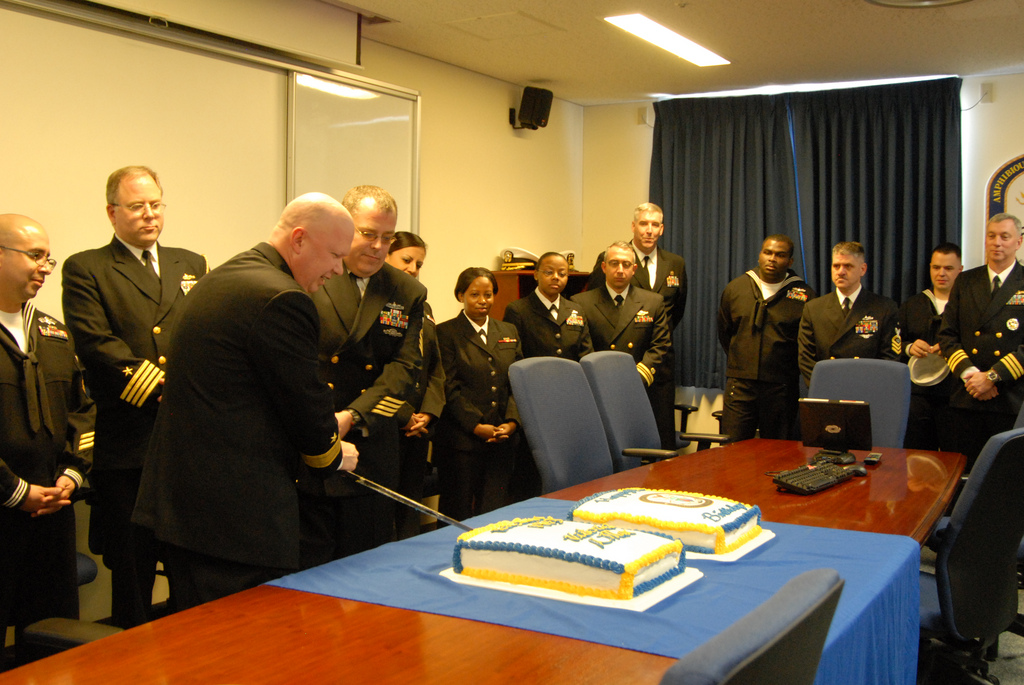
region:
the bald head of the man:
[275, 184, 362, 290]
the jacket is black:
[142, 258, 339, 538]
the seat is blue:
[502, 356, 623, 509]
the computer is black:
[790, 389, 888, 466]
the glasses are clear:
[24, 249, 60, 268]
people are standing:
[717, 209, 1022, 416]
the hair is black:
[446, 262, 495, 294]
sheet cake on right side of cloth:
[440, 508, 713, 617]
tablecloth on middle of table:
[265, 472, 934, 684]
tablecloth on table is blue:
[257, 472, 937, 684]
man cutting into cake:
[120, 186, 475, 611]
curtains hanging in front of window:
[635, 74, 980, 416]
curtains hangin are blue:
[635, 71, 980, 398]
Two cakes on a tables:
[582, 504, 691, 574]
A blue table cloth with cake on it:
[705, 576, 798, 624]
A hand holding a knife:
[339, 449, 358, 472]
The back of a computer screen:
[807, 401, 863, 443]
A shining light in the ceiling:
[637, 20, 660, 37]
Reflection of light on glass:
[302, 79, 329, 88]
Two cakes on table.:
[444, 476, 777, 613]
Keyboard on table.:
[769, 444, 859, 499]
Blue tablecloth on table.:
[784, 521, 931, 681]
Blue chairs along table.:
[509, 347, 668, 478]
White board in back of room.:
[273, 64, 423, 192]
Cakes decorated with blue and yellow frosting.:
[438, 472, 772, 619]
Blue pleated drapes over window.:
[649, 75, 967, 244]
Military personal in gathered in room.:
[0, 156, 1021, 479]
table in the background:
[74, 200, 1019, 653]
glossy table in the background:
[198, 271, 998, 649]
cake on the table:
[395, 420, 974, 639]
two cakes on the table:
[384, 398, 913, 661]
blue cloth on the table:
[258, 328, 907, 677]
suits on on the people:
[21, 40, 841, 544]